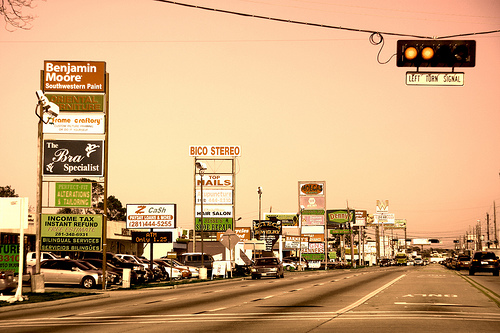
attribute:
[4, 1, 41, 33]
braches — bare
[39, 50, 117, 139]
sign — tall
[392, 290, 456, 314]
arrow in the street — white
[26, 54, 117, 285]
billboard — tall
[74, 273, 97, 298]
tire on the car — black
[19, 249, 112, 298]
parked car — grey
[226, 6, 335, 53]
electrical line — black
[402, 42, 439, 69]
traffic lights — yellow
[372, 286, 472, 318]
arrow on road — white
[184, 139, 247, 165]
red letters — white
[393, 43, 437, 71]
light on a pole — traffic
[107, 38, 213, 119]
clouds in blue sky — white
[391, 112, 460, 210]
clouds in blue — white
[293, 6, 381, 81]
clouds in blue sk — white